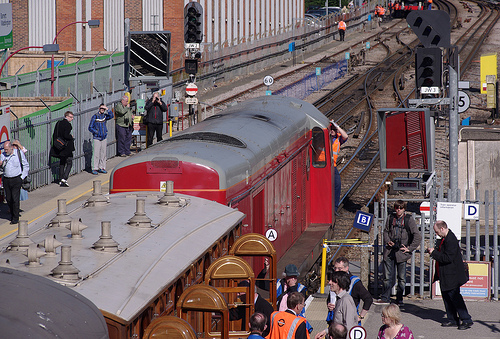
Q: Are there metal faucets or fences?
A: Yes, there is a metal fence.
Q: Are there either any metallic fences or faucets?
A: Yes, there is a metal fence.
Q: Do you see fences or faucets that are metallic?
A: Yes, the fence is metallic.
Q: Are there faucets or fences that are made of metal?
A: Yes, the fence is made of metal.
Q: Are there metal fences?
A: Yes, there is a fence that is made of metal.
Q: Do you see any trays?
A: No, there are no trays.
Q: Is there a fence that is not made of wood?
A: Yes, there is a fence that is made of metal.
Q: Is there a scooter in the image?
A: No, there are no scooters.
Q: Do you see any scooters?
A: No, there are no scooters.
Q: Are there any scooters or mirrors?
A: No, there are no scooters or mirrors.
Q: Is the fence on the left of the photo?
A: Yes, the fence is on the left of the image.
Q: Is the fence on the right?
A: No, the fence is on the left of the image.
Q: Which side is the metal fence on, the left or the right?
A: The fence is on the left of the image.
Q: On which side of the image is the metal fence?
A: The fence is on the left of the image.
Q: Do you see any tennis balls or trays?
A: No, there are no trays or tennis balls.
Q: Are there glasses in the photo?
A: No, there are no glasses.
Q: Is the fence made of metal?
A: Yes, the fence is made of metal.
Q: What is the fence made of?
A: The fence is made of metal.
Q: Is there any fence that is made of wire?
A: No, there is a fence but it is made of metal.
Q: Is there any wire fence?
A: No, there is a fence but it is made of metal.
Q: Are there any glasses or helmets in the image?
A: No, there are no glasses or helmets.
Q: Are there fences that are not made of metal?
A: No, there is a fence but it is made of metal.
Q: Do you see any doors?
A: Yes, there is a door.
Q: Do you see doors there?
A: Yes, there is a door.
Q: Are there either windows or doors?
A: Yes, there is a door.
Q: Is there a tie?
A: No, there are no ties.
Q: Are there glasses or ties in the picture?
A: No, there are no ties or glasses.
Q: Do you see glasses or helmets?
A: No, there are no glasses or helmets.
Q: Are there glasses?
A: No, there are no glasses.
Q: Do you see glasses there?
A: No, there are no glasses.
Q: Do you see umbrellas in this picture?
A: No, there are no umbrellas.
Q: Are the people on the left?
A: Yes, the people are on the left of the image.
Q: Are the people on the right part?
A: No, the people are on the left of the image.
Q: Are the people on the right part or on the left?
A: The people are on the left of the image.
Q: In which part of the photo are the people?
A: The people are on the left of the image.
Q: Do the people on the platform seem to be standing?
A: Yes, the people are standing.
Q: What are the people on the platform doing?
A: The people are standing.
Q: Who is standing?
A: The people are standing.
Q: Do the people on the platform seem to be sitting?
A: No, the people are standing.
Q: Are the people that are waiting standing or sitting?
A: The people are standing.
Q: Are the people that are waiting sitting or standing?
A: The people are standing.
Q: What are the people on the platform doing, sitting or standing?
A: The people are standing.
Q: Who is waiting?
A: The people are waiting.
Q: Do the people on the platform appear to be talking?
A: No, the people are waiting.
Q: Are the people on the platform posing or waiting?
A: The people are waiting.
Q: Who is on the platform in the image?
A: The people are on the platform.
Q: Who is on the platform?
A: The people are on the platform.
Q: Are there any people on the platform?
A: Yes, there are people on the platform.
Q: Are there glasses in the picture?
A: No, there are no glasses.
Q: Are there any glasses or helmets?
A: No, there are no glasses or helmets.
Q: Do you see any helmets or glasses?
A: No, there are no glasses or helmets.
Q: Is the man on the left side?
A: Yes, the man is on the left of the image.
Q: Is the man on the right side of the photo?
A: No, the man is on the left of the image.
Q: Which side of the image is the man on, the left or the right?
A: The man is on the left of the image.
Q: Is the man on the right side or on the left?
A: The man is on the left of the image.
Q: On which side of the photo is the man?
A: The man is on the left of the image.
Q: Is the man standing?
A: Yes, the man is standing.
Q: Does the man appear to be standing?
A: Yes, the man is standing.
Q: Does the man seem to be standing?
A: Yes, the man is standing.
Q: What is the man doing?
A: The man is standing.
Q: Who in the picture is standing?
A: The man is standing.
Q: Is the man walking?
A: No, the man is standing.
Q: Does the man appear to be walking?
A: No, the man is standing.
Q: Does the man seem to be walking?
A: No, the man is standing.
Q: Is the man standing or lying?
A: The man is standing.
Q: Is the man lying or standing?
A: The man is standing.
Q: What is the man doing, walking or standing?
A: The man is standing.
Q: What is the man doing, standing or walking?
A: The man is standing.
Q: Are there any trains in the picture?
A: Yes, there is a train.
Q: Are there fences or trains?
A: Yes, there is a train.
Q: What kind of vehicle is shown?
A: The vehicle is a train.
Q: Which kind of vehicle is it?
A: The vehicle is a train.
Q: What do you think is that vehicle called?
A: This is a train.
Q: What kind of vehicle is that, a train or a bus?
A: This is a train.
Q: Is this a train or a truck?
A: This is a train.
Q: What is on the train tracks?
A: The train is on the train tracks.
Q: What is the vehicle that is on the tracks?
A: The vehicle is a train.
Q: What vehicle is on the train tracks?
A: The vehicle is a train.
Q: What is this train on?
A: The train is on the train tracks.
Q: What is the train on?
A: The train is on the train tracks.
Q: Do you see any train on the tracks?
A: Yes, there is a train on the tracks.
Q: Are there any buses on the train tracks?
A: No, there is a train on the train tracks.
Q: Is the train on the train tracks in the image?
A: Yes, the train is on the train tracks.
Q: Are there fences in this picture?
A: Yes, there is a fence.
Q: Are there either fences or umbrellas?
A: Yes, there is a fence.